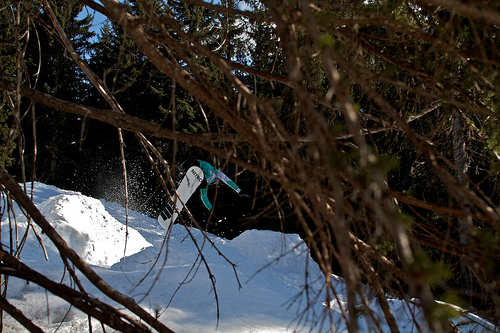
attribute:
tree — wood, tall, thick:
[1, 2, 497, 332]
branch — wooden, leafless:
[1, 76, 498, 274]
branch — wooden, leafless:
[100, 1, 266, 155]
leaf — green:
[364, 153, 404, 175]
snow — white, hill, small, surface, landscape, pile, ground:
[0, 178, 495, 331]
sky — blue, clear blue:
[73, 2, 136, 84]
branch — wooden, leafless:
[331, 49, 500, 222]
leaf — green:
[388, 208, 416, 229]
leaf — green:
[313, 31, 335, 51]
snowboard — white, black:
[157, 164, 204, 228]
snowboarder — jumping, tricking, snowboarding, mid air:
[192, 159, 252, 216]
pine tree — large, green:
[79, 16, 123, 105]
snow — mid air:
[104, 153, 167, 231]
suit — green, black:
[188, 157, 250, 212]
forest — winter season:
[1, 1, 498, 324]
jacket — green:
[199, 159, 241, 212]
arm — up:
[215, 166, 241, 193]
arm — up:
[201, 186, 213, 210]